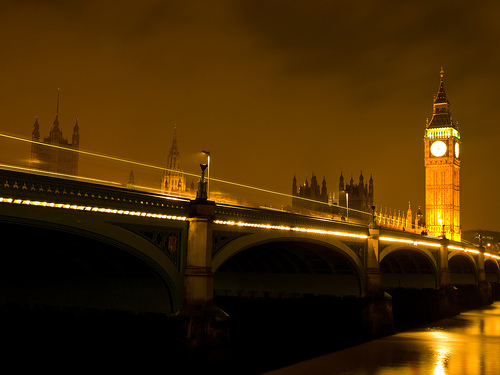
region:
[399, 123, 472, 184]
The clock on the tower.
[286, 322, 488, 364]
Water under the bridge.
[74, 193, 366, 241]
Lights on the edge of the bridge.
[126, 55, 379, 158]
The sky is dark.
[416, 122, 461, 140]
Lights on top of the tower.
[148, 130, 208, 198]
Tall building in the background.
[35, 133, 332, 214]
Lights on top of the freeway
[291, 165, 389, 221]
A castle looking building across the bridge.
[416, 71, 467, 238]
A tall tower with a clock on it.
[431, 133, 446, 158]
The face of the clock is white.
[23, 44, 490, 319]
a bridge next to a clock tower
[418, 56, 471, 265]
Big Ben clock tower in London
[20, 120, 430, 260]
the bridge is lit up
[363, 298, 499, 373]
the light is reflecting off of the water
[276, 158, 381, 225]
buildings in the background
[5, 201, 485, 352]
arches on the bridge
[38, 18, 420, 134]
a cloudy night sky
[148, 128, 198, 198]
the top of a structure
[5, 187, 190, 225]
lights on the side of the bridge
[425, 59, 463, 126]
the top of the clock tower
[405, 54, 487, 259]
Big Ben in London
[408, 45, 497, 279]
a large clock tower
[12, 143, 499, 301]
a large bridge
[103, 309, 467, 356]
water in the shadows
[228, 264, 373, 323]
shadows beneath the bridge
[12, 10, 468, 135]
the night sky is overcast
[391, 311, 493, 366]
reflections of the light in the river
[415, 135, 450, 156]
a brightly lit clock face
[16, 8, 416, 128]
an overcast evening sky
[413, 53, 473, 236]
a brightly lit clock tower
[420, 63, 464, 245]
An illumnated clock tower.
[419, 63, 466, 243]
Big Ben, a clock tower in London.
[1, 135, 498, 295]
A roadway going over the river.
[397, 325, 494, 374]
A patch of river with reflected light.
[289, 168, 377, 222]
A castle like structure.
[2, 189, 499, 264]
Yellow lights along the bridge.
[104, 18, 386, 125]
A patch of cloudy night sky.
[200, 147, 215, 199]
A night lamp on the roadeway.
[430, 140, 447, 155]
An illuminated clock face.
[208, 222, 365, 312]
An archway over the river.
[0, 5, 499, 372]
scenery during the end of sundown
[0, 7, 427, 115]
Sky with partial clouds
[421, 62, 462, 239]
A luminous clock tower at night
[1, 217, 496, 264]
A bridge leading into the city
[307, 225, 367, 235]
lights along deck of bridge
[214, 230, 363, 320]
one of five arches is shown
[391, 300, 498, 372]
tower reflects on water below left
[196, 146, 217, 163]
a street lamp to light the street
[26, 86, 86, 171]
a tall building with lighted tips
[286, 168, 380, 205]
designs top of a building